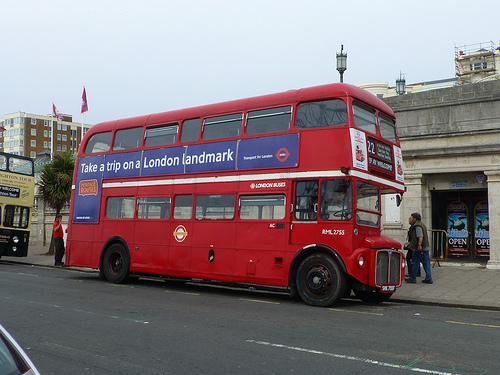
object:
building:
[0, 111, 94, 213]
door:
[431, 190, 491, 266]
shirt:
[407, 221, 433, 253]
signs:
[444, 198, 471, 265]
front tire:
[295, 252, 346, 307]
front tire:
[352, 284, 392, 302]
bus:
[65, 82, 407, 307]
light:
[331, 42, 351, 83]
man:
[404, 212, 434, 284]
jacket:
[406, 221, 428, 248]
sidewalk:
[392, 261, 497, 299]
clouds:
[362, 7, 422, 63]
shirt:
[52, 221, 63, 240]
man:
[51, 213, 63, 266]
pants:
[53, 238, 66, 265]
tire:
[101, 241, 129, 283]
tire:
[156, 276, 184, 288]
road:
[3, 261, 498, 372]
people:
[403, 212, 433, 285]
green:
[399, 356, 490, 374]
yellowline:
[445, 319, 499, 329]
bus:
[0, 152, 35, 262]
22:
[368, 141, 377, 154]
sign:
[71, 133, 300, 224]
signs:
[475, 201, 489, 261]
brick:
[447, 275, 498, 308]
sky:
[0, 0, 496, 146]